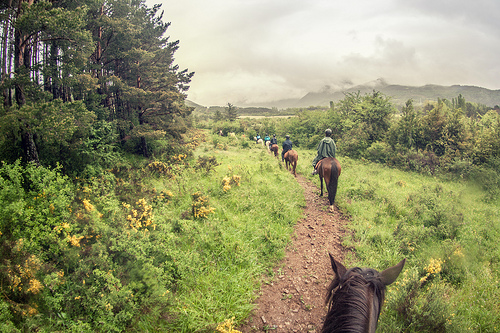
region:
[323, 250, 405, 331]
back of horse's head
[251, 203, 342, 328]
a brown dirt trail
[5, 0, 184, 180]
tall green pine trees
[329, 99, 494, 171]
clump of green bushes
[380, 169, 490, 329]
tall grass with yellow flowers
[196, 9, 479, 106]
cloudy gray sky over hills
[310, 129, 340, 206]
person riding brown horse with black tail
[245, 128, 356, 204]
line of people on horseback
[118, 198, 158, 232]
clump of yellow flowers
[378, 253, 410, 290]
right ear of horse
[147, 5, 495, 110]
large curved clouds bordered in gray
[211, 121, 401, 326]
horses and riders following curved dirt path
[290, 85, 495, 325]
grasses along path bordering row of bushes and trees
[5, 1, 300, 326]
wide swath of bushy plant growth to evergreen border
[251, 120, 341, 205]
riders in single file in line of dirt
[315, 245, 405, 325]
dark horse with dark mane coming into view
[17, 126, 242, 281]
plant with yellow leaves spaced throughout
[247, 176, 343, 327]
fallen leaves and stones on path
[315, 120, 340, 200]
rider draped in green cape on brown horse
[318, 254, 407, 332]
horse walking on a dirt path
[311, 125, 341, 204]
man riding a horse on a dirt path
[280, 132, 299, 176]
man riding a horse on a dirt path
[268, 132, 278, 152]
man riding a horse on a dirt path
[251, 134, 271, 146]
people riding horses on a dirt path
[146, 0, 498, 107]
white cloudy sky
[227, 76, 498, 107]
a mountain range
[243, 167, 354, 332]
dirt path through the countryside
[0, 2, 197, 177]
row of trees beside a path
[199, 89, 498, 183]
bushes growing beside dirt path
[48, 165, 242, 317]
The grass is tall and green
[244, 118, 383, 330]
People on a horse trail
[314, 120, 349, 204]
The person is on a horse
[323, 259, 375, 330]
The mane of the horse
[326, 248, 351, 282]
The ear of the horse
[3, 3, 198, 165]
The trees are very tall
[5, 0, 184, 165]
The trees are the color green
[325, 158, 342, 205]
The tail of the horse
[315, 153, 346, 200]
The color of the horse is brown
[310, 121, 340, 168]
person in green on a horse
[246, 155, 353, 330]
dirt trail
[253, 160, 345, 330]
trail for riding horses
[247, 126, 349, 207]
people riding horses over a dirt path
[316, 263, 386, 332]
mane of a dark colored horse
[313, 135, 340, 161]
green colored robe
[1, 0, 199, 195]
wall of pine trees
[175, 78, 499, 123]
mountains in the distance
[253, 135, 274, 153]
two light colored horses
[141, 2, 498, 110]
a hazy sky over head